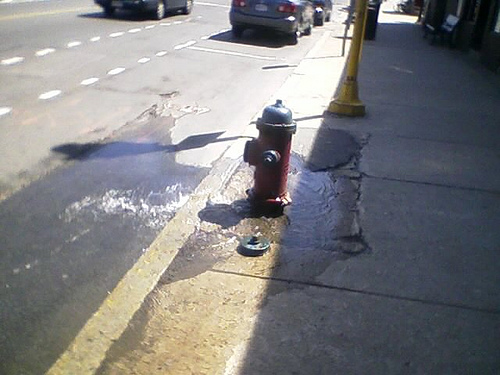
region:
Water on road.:
[71, 25, 228, 251]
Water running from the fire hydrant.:
[136, 95, 291, 250]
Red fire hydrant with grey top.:
[201, 76, 306, 216]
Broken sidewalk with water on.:
[297, 112, 453, 298]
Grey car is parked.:
[215, 0, 361, 67]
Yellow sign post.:
[315, 0, 416, 135]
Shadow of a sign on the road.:
[36, 102, 246, 187]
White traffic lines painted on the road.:
[0, 10, 240, 120]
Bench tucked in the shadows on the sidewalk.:
[395, 2, 476, 52]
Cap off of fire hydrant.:
[75, 132, 290, 282]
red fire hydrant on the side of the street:
[223, 95, 297, 210]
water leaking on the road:
[93, 119, 223, 241]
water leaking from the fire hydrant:
[123, 89, 305, 270]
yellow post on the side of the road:
[316, 0, 379, 111]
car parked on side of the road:
[215, 0, 302, 45]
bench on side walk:
[420, 10, 462, 45]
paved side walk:
[387, 106, 499, 316]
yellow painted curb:
[147, 151, 237, 289]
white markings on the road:
[76, 42, 157, 86]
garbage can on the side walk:
[361, 6, 384, 38]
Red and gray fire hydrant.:
[241, 93, 315, 223]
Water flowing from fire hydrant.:
[82, 178, 244, 230]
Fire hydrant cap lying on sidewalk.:
[232, 229, 279, 256]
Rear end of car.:
[228, 1, 313, 43]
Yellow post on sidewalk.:
[327, 3, 378, 120]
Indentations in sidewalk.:
[354, 161, 490, 346]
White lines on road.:
[36, 29, 172, 108]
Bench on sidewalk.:
[420, 11, 462, 51]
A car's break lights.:
[276, 2, 300, 18]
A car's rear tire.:
[225, 23, 248, 41]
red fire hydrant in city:
[222, 90, 318, 280]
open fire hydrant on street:
[143, 97, 353, 290]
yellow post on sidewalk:
[302, 10, 393, 115]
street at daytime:
[18, 17, 151, 117]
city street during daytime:
[110, 5, 346, 338]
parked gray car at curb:
[212, 0, 323, 57]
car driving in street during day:
[70, 0, 210, 36]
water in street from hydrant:
[63, 130, 169, 271]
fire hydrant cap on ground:
[232, 218, 279, 273]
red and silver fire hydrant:
[233, 93, 304, 286]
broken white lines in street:
[28, 28, 160, 80]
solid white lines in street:
[198, 41, 301, 74]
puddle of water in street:
[93, 165, 183, 246]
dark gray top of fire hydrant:
[255, 97, 304, 137]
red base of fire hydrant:
[243, 125, 310, 199]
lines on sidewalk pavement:
[391, 162, 495, 210]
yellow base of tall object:
[315, 85, 379, 117]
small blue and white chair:
[425, 7, 467, 48]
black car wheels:
[289, 29, 306, 46]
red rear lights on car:
[274, 3, 304, 18]